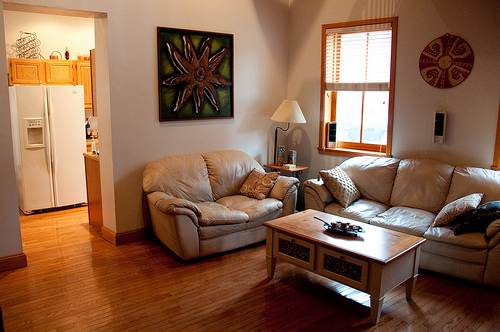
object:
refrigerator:
[8, 85, 88, 215]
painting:
[157, 26, 234, 121]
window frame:
[317, 17, 399, 157]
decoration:
[418, 33, 475, 89]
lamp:
[269, 95, 306, 164]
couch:
[142, 150, 300, 262]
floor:
[1, 204, 498, 331]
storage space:
[9, 58, 78, 86]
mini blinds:
[323, 21, 393, 83]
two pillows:
[430, 192, 500, 236]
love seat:
[142, 149, 301, 260]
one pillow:
[238, 168, 281, 199]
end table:
[264, 163, 310, 172]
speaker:
[431, 111, 447, 145]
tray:
[313, 216, 365, 236]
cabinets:
[9, 58, 92, 149]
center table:
[260, 207, 429, 326]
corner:
[258, 0, 313, 162]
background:
[2, 2, 113, 267]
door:
[15, 85, 55, 210]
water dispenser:
[22, 117, 45, 148]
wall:
[107, 1, 500, 247]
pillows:
[318, 166, 361, 208]